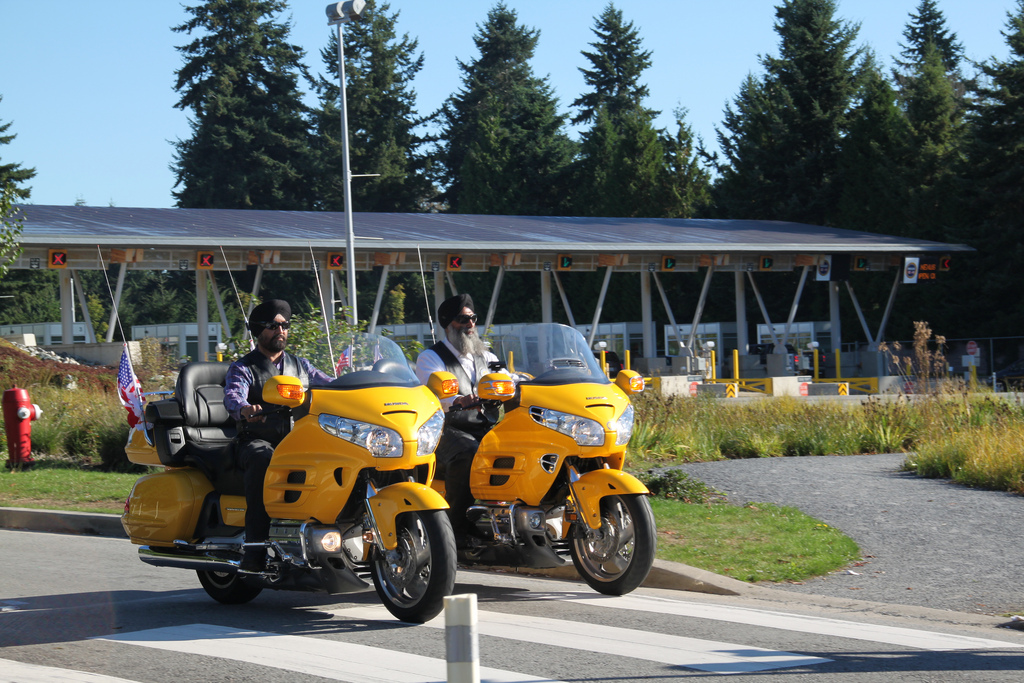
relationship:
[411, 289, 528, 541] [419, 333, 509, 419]
man wearing shirt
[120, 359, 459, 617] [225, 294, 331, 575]
bike ridden by man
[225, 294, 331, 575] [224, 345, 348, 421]
man wearing shirt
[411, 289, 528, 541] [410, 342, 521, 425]
man in shirt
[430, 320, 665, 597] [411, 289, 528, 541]
motorcycle ridden by man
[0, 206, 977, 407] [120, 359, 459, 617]
shelter behind bike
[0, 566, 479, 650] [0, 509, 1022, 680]
shadows on road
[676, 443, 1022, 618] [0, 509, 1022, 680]
path next to road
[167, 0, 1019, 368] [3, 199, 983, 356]
trees behind shelter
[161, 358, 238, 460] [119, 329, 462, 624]
seat on motorcycle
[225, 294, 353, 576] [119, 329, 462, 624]
man on motorcycle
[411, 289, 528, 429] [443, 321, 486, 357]
man has beard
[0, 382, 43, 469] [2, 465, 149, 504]
fire hydrant on grass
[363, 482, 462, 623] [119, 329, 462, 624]
wheel of motorcycle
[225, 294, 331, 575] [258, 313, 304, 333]
man wearing sunglasses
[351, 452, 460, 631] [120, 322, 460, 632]
tire on bike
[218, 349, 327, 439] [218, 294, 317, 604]
shirt on man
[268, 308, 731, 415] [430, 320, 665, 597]
shield on motorcycle